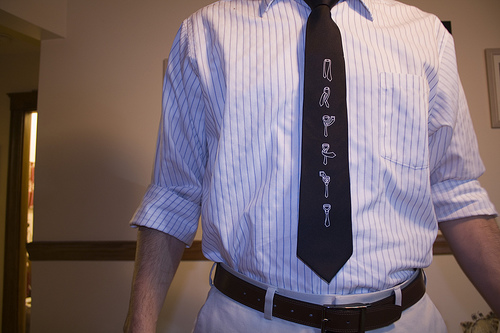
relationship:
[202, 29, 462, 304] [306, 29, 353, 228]
man wearing tie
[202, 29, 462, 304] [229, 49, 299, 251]
man wearing shirt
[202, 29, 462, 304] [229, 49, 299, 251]
man in shirt